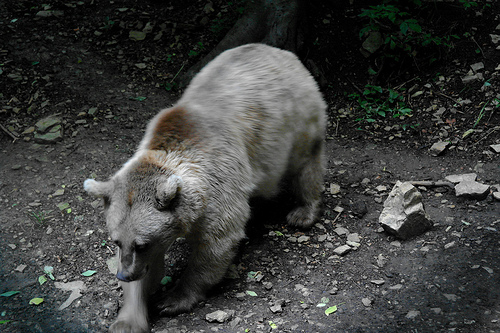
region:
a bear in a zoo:
[31, 40, 358, 329]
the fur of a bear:
[189, 102, 281, 169]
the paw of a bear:
[283, 208, 318, 235]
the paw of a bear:
[154, 290, 189, 313]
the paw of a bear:
[105, 309, 150, 331]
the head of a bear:
[73, 175, 186, 283]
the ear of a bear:
[153, 176, 179, 208]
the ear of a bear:
[76, 172, 112, 204]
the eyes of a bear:
[108, 232, 151, 256]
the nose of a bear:
[113, 258, 135, 285]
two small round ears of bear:
[77, 170, 194, 207]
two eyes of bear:
[109, 235, 149, 255]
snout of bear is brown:
[111, 245, 148, 287]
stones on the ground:
[360, 165, 490, 240]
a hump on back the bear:
[146, 99, 203, 162]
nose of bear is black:
[114, 269, 136, 284]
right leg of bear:
[166, 232, 237, 317]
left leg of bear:
[108, 273, 153, 328]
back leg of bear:
[283, 148, 333, 233]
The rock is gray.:
[427, 136, 451, 155]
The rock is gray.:
[451, 175, 490, 198]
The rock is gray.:
[440, 169, 482, 186]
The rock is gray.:
[375, 177, 437, 240]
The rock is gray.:
[328, 175, 344, 196]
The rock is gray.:
[331, 223, 351, 240]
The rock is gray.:
[332, 238, 352, 258]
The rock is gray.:
[202, 305, 238, 329]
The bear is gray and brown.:
[73, 35, 333, 331]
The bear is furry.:
[78, 35, 336, 331]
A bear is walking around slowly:
[37, 6, 493, 331]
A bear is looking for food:
[26, 16, 476, 324]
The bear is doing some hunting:
[40, 18, 468, 329]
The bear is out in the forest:
[35, 17, 445, 329]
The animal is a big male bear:
[52, 27, 417, 329]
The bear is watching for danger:
[51, 35, 404, 331]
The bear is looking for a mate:
[40, 16, 495, 329]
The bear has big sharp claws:
[27, 27, 444, 330]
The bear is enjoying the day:
[45, 24, 390, 322]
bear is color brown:
[74, 28, 341, 327]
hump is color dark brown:
[137, 94, 207, 170]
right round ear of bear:
[154, 173, 189, 205]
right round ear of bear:
[76, 176, 118, 202]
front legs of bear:
[101, 262, 224, 330]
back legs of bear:
[262, 148, 333, 231]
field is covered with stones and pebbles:
[0, 0, 494, 330]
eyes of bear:
[110, 233, 148, 253]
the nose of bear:
[110, 270, 132, 285]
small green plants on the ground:
[351, 2, 436, 131]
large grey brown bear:
[83, 42, 327, 330]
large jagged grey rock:
[376, 181, 424, 238]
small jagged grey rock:
[202, 309, 232, 323]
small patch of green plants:
[352, 0, 438, 127]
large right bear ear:
[159, 176, 180, 210]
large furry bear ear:
[79, 174, 114, 200]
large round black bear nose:
[116, 268, 138, 281]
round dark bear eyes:
[112, 240, 154, 253]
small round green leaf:
[81, 266, 99, 276]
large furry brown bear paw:
[106, 307, 151, 332]